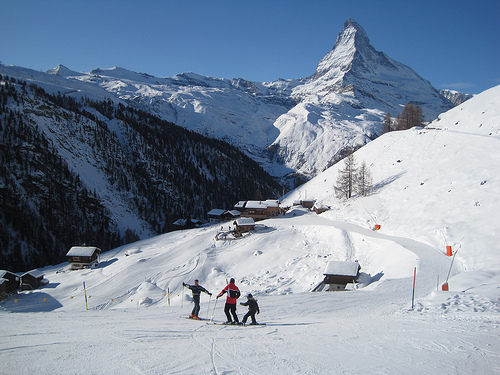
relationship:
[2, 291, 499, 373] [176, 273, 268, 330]
people enjoying slope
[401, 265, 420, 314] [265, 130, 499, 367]
flag on side of a slope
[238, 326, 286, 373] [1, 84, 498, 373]
track in snow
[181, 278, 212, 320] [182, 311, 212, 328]
people standing with skis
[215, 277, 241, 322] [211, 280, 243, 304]
person in coat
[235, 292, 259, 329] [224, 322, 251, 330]
child on skis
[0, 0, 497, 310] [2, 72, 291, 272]
mountainside filled with trees